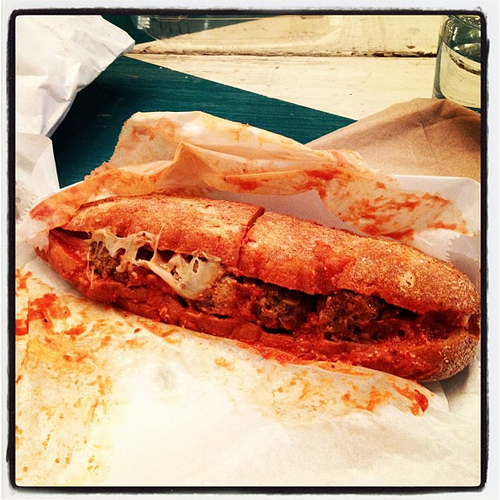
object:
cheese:
[83, 228, 219, 298]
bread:
[32, 189, 481, 379]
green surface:
[112, 67, 163, 88]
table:
[125, 15, 448, 119]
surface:
[5, 304, 93, 488]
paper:
[9, 16, 136, 271]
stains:
[371, 49, 437, 57]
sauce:
[18, 310, 82, 409]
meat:
[246, 291, 406, 342]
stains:
[14, 262, 131, 486]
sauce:
[357, 179, 420, 224]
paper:
[11, 356, 425, 483]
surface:
[157, 125, 329, 191]